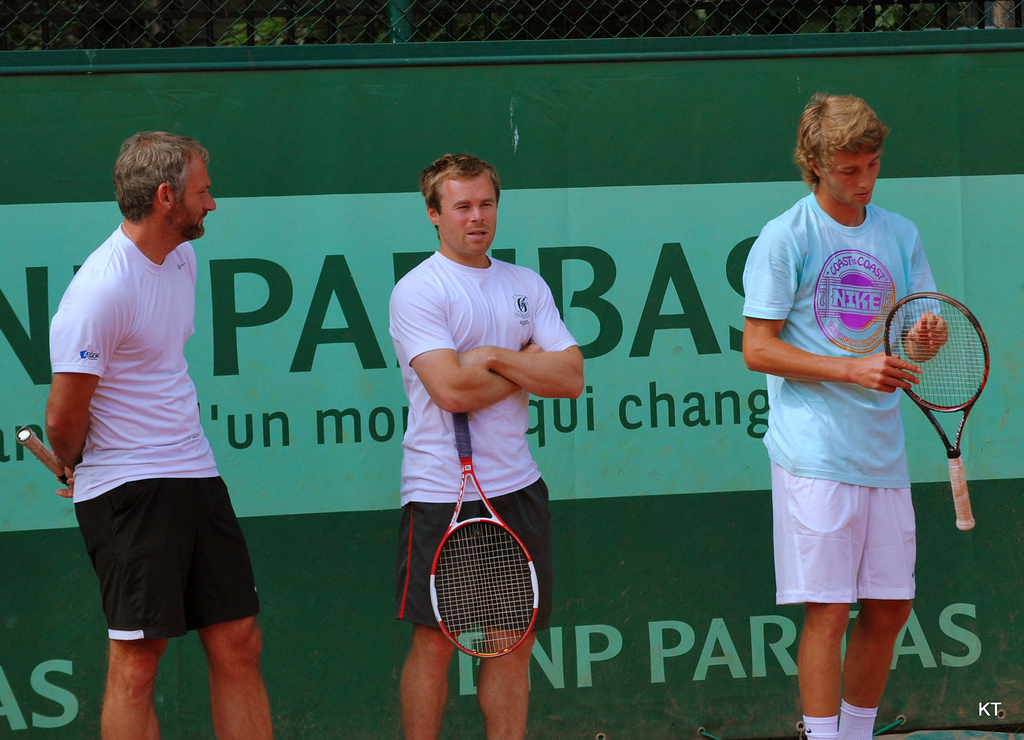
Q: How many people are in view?
A: 3.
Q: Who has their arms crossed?
A: The man in the middle.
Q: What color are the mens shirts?
A: White.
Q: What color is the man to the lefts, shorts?
A: Black.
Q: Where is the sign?
A: Behind the men.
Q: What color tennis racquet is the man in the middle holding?
A: Red and white.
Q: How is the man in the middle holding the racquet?
A: Upside down.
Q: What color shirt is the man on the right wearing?
A: Blue.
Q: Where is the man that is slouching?
A: Left side.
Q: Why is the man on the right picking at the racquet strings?
A: Adjusting them.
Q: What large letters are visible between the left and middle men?
A: PA.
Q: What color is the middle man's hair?
A: Brown.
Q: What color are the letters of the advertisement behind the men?
A: Green.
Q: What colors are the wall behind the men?
A: Dark and light green.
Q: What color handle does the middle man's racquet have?
A: Black.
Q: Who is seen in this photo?
A: Three Men.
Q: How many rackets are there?
A: Three.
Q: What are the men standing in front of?
A: A wall.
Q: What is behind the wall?
A: A chain link fence.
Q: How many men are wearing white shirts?
A: Two.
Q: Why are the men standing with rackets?
A: They are waiting to play tennis.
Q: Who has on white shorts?
A: The man on the far right.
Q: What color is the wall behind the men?
A: Green.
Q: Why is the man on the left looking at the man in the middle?
A: He is listening to him talk.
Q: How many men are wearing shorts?
A: Three.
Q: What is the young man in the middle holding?
A: Tennis racket.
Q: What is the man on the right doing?
A: Playing with the tennis racket.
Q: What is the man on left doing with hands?
A: Behind back.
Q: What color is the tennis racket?
A: Red.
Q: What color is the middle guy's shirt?
A: White.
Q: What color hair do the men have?
A: Blonde.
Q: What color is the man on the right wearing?
A: Blue.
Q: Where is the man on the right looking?
A: Down.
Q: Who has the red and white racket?
A: The man in the middle.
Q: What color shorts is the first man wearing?
A: Black.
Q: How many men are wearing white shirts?
A: Two.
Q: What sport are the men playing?
A: Tennis.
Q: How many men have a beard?
A: One.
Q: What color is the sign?
A: Green.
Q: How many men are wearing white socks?
A: One.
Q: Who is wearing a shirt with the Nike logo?
A: The man in the blue shirt.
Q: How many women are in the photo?
A: None.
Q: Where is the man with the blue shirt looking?
A: Down at the racket.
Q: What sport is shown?
A: Tennis.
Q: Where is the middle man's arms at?
A: Crossed on his chest.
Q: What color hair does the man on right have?
A: Blonde.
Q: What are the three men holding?
A: Tennis rackets.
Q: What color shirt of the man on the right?
A: Blue.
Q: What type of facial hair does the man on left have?
A: Beard.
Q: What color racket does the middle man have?
A: Red and white.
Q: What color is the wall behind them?
A: Green.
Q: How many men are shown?
A: Three.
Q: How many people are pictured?
A: Three.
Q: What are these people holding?
A: Tennis rackets.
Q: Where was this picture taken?
A: Tennis court.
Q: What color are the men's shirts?
A: White.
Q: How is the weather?
A: Clear.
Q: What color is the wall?
A: Green.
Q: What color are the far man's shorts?
A: Black.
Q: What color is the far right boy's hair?
A: Blonde.